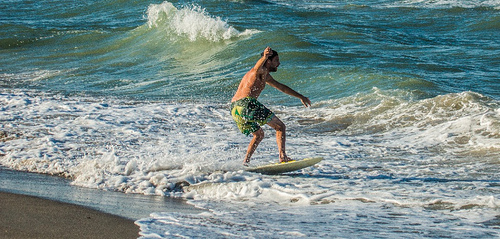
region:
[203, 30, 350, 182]
A man is surfing.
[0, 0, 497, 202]
The ocean is blue and white.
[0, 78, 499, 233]
The waves are hitting the shore.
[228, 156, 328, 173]
The surfboard is white.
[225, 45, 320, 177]
The man is on a surfboard.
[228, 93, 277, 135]
The man is wearing swim trunks.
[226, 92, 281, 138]
The swim trunks are green, yellow and black.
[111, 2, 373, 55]
A big wave is coming.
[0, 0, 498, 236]
The man is surfing close to the shore.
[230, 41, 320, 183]
The surfer is keeping balance.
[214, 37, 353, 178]
man on a surfboard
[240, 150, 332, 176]
board sticking out of the water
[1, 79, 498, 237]
shallow part of the water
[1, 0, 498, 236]
a body of water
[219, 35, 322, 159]
man is not wearing a shirt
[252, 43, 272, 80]
arm is lifted up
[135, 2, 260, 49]
small wave in the water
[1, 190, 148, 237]
sand on the shore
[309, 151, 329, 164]
tip of the board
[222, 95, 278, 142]
multicolored shorts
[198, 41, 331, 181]
A man surfing on the shore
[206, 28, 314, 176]
man is on surfboard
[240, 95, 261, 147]
blue and white shorts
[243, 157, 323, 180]
man on white surfboard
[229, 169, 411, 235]
white waves near shore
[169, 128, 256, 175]
white wake behind board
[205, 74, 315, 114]
man has arms extended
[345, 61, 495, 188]
small wave near man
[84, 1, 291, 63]
white wave in distance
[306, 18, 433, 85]
water is dark blue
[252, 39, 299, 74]
man has dark hair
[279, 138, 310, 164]
edge of a bard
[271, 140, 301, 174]
edge of a board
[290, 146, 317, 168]
part of a board